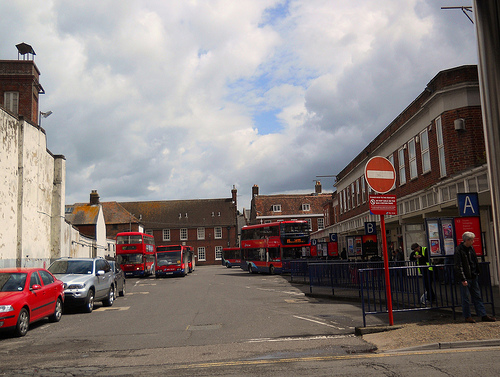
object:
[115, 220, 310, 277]
buses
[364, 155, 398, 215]
sign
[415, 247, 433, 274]
vest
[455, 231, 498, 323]
man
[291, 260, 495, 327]
fence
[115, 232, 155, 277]
bus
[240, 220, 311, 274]
bus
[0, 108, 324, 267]
wall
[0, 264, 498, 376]
ground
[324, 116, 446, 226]
window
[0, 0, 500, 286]
building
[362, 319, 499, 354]
sidewalk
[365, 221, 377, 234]
b sign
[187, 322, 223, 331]
pothole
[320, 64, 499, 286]
red buildings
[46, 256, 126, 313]
vehicle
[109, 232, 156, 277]
vehicle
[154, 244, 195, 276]
vehicle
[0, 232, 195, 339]
row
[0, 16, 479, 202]
sky